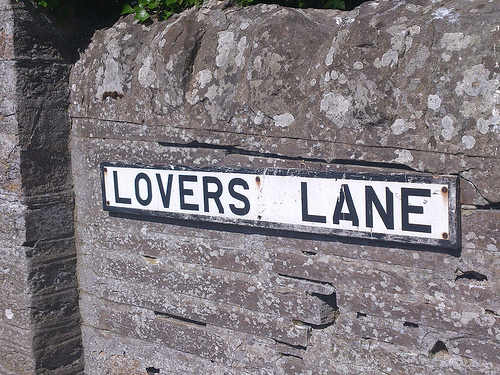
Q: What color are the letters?
A: Black.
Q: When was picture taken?
A: Daytime.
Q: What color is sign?
A: White.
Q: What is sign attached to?
A: Wall.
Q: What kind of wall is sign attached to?
A: Brick.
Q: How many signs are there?
A: One.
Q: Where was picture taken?
A: Near sign.